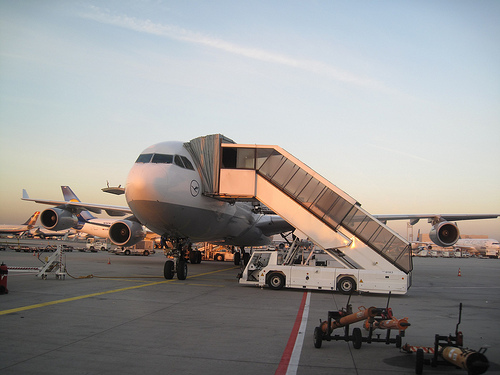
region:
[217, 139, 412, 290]
stairs attached to plane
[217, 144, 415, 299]
vehicle has stairs pulled up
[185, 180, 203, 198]
black logo on plane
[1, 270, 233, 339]
yellow line on pavement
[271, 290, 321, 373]
red and white lines on pavement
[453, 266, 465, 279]
orange and white cone on pavement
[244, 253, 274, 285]
vehicle seat is empty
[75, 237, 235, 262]
vehicles behind the plane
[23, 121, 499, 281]
plane is not moving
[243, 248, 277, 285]
vehicle has no door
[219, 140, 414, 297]
White stairway on side of door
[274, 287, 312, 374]
Red and white stripe on runway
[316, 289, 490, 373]
Machinery next to plane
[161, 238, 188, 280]
Landing gear under nose of plane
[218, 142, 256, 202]
White door on side of plane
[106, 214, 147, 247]
Engine under wing of plane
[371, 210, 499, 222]
Wing on side of plane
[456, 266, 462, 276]
Traffic cone sitting on the runway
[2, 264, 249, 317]
Yellow stripe on runway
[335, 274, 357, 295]
Wheel on back of vehicle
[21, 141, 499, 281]
white and grey plane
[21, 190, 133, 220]
grey wing on plane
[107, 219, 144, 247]
booster jet on plane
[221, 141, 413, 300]
stairs to board plane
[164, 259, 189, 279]
black tires on plane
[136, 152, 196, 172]
cock pit windows of plane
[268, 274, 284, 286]
black tire of truck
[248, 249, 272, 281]
door on white truck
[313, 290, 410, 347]
metal carts on runway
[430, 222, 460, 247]
booster barrel on plane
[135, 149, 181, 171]
Large clear windshield on front of plane.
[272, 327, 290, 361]
Red line marking pavement.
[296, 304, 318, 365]
White line marking pavement.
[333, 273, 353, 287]
Black wheel on white vehicle.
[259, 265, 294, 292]
Black wheel on white vehicle.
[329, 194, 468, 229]
Large wing on side of plane.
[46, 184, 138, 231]
Large wing on side of plane.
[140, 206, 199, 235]
Bottom of plane is gray.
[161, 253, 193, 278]
Black wheel on bottom of plane.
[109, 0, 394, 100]
one long cloud in sky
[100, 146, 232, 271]
plane on the runway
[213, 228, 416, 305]
vehicle next to plane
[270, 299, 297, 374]
stripe on the runway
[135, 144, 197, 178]
window of the plane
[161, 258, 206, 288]
wheels of the plane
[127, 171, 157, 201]
nose of the plane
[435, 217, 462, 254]
engine on the plane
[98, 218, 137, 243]
engine of the plane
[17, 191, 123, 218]
wing of the plane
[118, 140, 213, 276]
The plane on the terminal.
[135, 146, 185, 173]
The cockpit on the plane.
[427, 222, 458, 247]
The engine under the wing.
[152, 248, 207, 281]
The landing gear of the plane.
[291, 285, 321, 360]
The lines are red and white.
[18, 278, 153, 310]
The line is yellow.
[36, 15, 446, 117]
The sky is cloudy and blue.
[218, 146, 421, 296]
A stairway to the airplane.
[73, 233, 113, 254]
A truck on the runway.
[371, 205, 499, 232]
The wing of the plane.